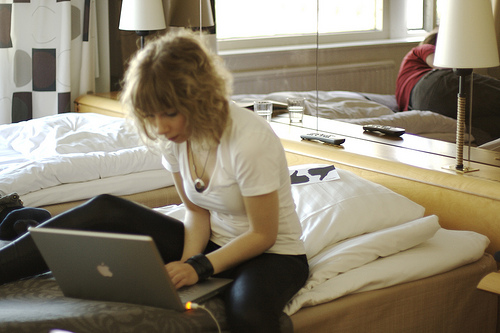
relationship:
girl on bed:
[0, 30, 312, 331] [2, 108, 473, 330]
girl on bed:
[0, 30, 312, 331] [0, 123, 500, 331]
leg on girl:
[224, 242, 311, 329] [0, 30, 312, 331]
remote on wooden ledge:
[300, 133, 345, 145] [78, 83, 498, 243]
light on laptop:
[183, 300, 194, 310] [25, 210, 240, 319]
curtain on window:
[0, 4, 117, 124] [200, 0, 435, 58]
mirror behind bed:
[103, 2, 499, 167] [1, 156, 496, 330]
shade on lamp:
[430, 2, 499, 76] [430, 2, 498, 178]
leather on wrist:
[187, 253, 214, 281] [165, 253, 218, 286]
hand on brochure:
[308, 164, 335, 180] [288, 164, 340, 185]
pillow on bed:
[289, 164, 424, 252] [0, 202, 497, 327]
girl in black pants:
[0, 30, 312, 331] [0, 193, 313, 333]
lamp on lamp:
[430, 0, 498, 179] [443, 68, 477, 173]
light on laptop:
[185, 301, 192, 310] [28, 224, 228, 302]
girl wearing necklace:
[0, 30, 312, 331] [185, 130, 215, 192]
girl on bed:
[0, 30, 312, 331] [1, 156, 496, 330]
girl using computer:
[0, 30, 312, 331] [24, 225, 235, 309]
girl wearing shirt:
[0, 30, 312, 331] [223, 108, 290, 204]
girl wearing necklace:
[0, 30, 312, 331] [187, 138, 218, 194]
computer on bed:
[24, 227, 234, 312] [309, 181, 484, 321]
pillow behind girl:
[290, 158, 430, 253] [120, 34, 318, 324]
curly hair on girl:
[121, 29, 230, 147] [0, 30, 312, 331]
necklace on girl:
[187, 138, 218, 194] [0, 30, 312, 331]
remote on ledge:
[302, 129, 346, 146] [398, 159, 498, 220]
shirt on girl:
[132, 102, 313, 257] [120, 34, 318, 324]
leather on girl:
[183, 255, 215, 283] [111, 27, 323, 283]